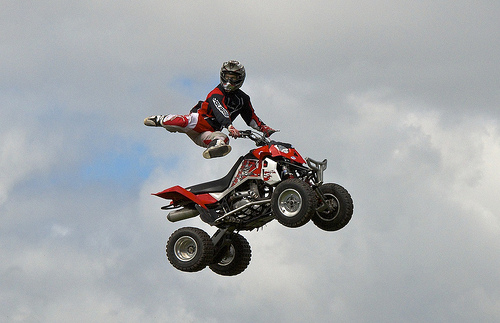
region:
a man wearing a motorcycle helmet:
[215, 56, 254, 96]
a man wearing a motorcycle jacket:
[185, 78, 268, 133]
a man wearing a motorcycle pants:
[141, 103, 239, 163]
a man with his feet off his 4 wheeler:
[134, 50, 276, 170]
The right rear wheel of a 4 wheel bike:
[161, 221, 213, 276]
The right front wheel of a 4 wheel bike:
[266, 175, 317, 230]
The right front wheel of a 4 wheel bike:
[304, 176, 359, 234]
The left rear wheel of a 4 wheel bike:
[199, 223, 255, 285]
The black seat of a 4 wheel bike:
[181, 152, 251, 204]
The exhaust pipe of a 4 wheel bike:
[154, 199, 204, 226]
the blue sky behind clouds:
[42, 91, 144, 223]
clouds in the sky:
[323, 24, 498, 254]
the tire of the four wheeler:
[168, 226, 213, 270]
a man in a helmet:
[151, 61, 281, 147]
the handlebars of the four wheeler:
[228, 128, 290, 150]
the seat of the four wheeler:
[187, 165, 246, 189]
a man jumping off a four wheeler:
[144, 58, 362, 272]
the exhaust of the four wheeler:
[170, 205, 200, 218]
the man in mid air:
[145, 60, 280, 158]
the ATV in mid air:
[150, 128, 354, 276]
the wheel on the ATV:
[164, 225, 211, 272]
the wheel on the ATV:
[209, 230, 251, 274]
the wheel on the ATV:
[270, 178, 317, 228]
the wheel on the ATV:
[312, 180, 354, 230]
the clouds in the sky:
[0, 0, 496, 322]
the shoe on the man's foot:
[145, 113, 166, 128]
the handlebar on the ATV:
[229, 126, 281, 145]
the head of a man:
[201, 58, 268, 100]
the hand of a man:
[215, 108, 260, 141]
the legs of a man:
[156, 109, 247, 171]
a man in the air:
[123, 33, 319, 182]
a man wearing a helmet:
[211, 43, 282, 105]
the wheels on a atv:
[141, 105, 381, 290]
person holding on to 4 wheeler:
[102, 26, 355, 293]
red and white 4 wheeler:
[149, 120, 346, 282]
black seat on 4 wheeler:
[176, 146, 258, 223]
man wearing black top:
[187, 77, 259, 127]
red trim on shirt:
[198, 86, 262, 134]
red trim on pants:
[158, 103, 231, 153]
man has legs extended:
[145, 95, 240, 165]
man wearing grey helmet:
[209, 50, 251, 90]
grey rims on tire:
[274, 183, 310, 220]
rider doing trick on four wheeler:
[130, 46, 290, 159]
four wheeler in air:
[149, 116, 359, 291]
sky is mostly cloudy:
[1, 1, 498, 322]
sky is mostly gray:
[1, 3, 498, 322]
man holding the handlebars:
[225, 120, 282, 150]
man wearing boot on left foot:
[200, 135, 232, 158]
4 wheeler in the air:
[153, 128, 353, 290]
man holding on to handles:
[125, 34, 354, 286]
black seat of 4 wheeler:
[180, 149, 249, 199]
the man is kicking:
[128, 37, 292, 172]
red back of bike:
[146, 174, 210, 216]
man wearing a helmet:
[212, 60, 254, 93]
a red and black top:
[188, 80, 253, 130]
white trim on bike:
[222, 150, 289, 192]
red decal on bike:
[220, 151, 274, 193]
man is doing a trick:
[140, 51, 351, 280]